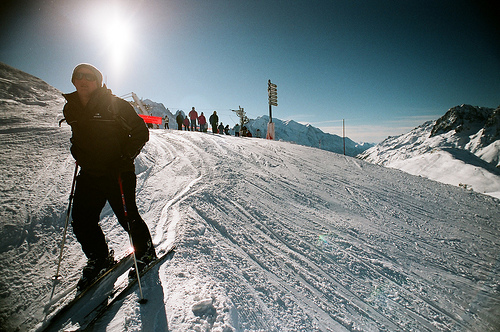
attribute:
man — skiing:
[49, 57, 164, 283]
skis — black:
[40, 245, 173, 329]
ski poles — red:
[46, 166, 140, 308]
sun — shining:
[57, 8, 155, 73]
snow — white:
[174, 141, 491, 297]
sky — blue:
[46, 5, 496, 128]